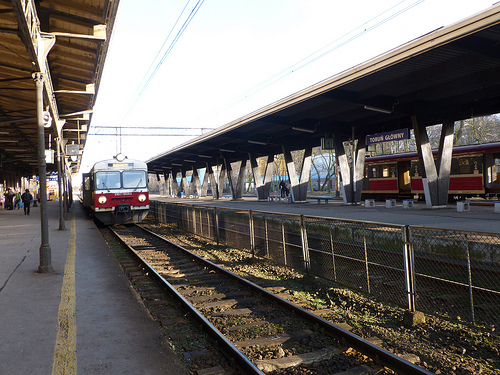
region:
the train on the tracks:
[81, 158, 161, 237]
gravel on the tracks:
[217, 307, 277, 353]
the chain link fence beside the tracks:
[177, 192, 494, 330]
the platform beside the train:
[12, 188, 150, 371]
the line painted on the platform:
[46, 263, 114, 373]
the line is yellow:
[34, 260, 87, 370]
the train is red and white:
[81, 148, 167, 224]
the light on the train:
[110, 150, 133, 163]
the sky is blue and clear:
[228, 16, 309, 58]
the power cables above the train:
[113, 0, 203, 135]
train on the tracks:
[84, 153, 161, 226]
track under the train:
[123, 230, 168, 285]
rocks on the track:
[203, 276, 251, 331]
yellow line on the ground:
[33, 288, 95, 348]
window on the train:
[101, 168, 143, 191]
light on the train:
[93, 185, 115, 216]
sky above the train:
[197, 6, 261, 73]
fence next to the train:
[234, 202, 287, 247]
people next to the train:
[6, 180, 36, 219]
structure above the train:
[333, 43, 391, 96]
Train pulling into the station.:
[84, 149, 162, 229]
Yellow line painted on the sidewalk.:
[59, 227, 83, 374]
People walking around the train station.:
[2, 182, 38, 217]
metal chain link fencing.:
[170, 198, 497, 328]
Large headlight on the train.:
[111, 148, 128, 163]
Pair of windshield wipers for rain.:
[96, 176, 148, 193]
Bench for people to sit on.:
[293, 190, 345, 207]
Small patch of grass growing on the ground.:
[299, 288, 336, 310]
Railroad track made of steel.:
[118, 242, 329, 352]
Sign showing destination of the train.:
[106, 161, 136, 168]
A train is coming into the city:
[15, 25, 475, 350]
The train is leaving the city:
[10, 25, 465, 363]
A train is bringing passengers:
[8, 51, 484, 352]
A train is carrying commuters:
[6, 82, 457, 347]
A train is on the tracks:
[12, 61, 448, 349]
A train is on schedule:
[32, 63, 468, 358]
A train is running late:
[37, 55, 437, 350]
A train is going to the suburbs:
[6, 50, 427, 351]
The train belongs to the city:
[7, 52, 467, 337]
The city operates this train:
[17, 61, 455, 339]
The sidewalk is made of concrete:
[1, 217, 36, 362]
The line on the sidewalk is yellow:
[52, 233, 85, 373]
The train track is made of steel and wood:
[107, 237, 352, 371]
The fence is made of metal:
[218, 205, 490, 332]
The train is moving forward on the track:
[78, 150, 156, 232]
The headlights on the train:
[93, 190, 150, 207]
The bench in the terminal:
[295, 189, 346, 208]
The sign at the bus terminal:
[359, 125, 416, 148]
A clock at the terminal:
[317, 131, 337, 155]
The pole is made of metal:
[27, 61, 53, 278]